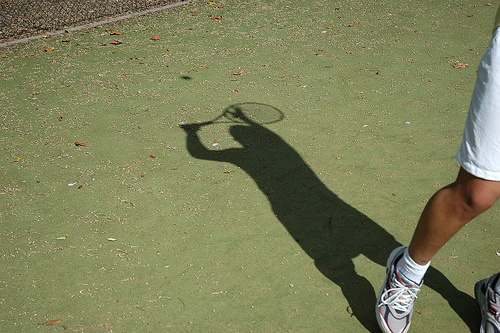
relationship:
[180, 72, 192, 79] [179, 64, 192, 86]
shadow of ball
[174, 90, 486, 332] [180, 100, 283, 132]
shadow of tennis racket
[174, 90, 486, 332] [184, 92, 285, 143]
shadow of a tennis racket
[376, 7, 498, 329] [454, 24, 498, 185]
person wearing shorts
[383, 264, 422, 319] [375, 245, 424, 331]
laces on shoe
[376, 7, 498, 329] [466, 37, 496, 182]
person wearing shorts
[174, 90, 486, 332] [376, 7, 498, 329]
shadow of person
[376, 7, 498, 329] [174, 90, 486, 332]
person casting shadow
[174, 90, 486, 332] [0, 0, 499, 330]
shadow on ground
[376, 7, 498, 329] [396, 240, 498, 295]
person wearing socks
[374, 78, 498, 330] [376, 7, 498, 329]
leg of person